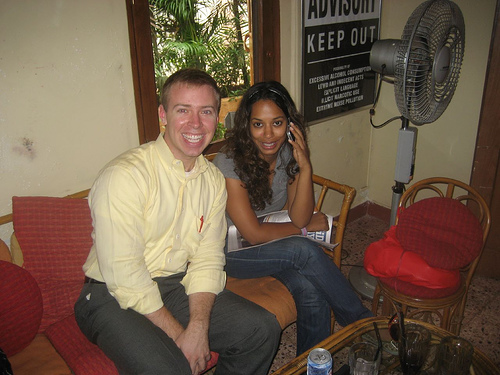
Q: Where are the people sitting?
A: Sofa.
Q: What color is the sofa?
A: Brown.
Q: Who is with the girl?
A: Man.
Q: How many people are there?
A: Two.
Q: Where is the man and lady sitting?
A: Couch.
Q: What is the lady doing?
A: Talking on phone.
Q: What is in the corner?
A: Fan.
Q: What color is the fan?
A: Silver.